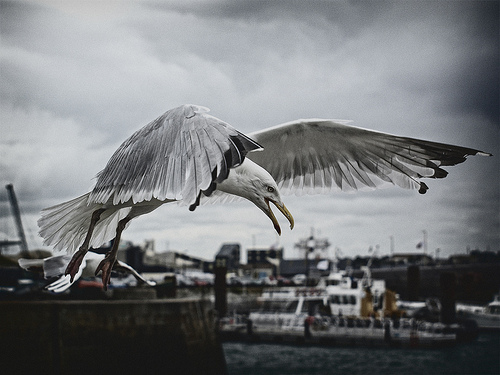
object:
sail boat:
[462, 294, 498, 328]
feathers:
[29, 102, 493, 255]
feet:
[48, 237, 100, 299]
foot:
[93, 235, 120, 295]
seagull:
[31, 85, 498, 296]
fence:
[0, 295, 224, 374]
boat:
[226, 265, 475, 347]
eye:
[262, 185, 277, 197]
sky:
[1, 0, 499, 262]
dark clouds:
[403, 100, 484, 142]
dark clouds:
[395, 36, 477, 88]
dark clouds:
[248, 27, 323, 74]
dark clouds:
[128, 21, 191, 82]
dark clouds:
[0, 0, 98, 72]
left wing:
[235, 118, 493, 197]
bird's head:
[217, 160, 295, 235]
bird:
[15, 98, 492, 297]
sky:
[0, 0, 492, 239]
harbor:
[154, 266, 328, 355]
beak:
[259, 193, 298, 237]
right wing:
[89, 98, 266, 210]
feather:
[215, 126, 253, 166]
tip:
[242, 134, 266, 157]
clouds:
[0, 0, 497, 256]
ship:
[420, 285, 498, 336]